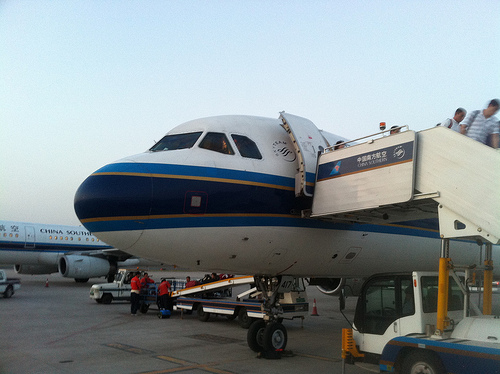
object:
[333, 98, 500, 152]
passenger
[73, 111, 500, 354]
plane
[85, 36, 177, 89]
sky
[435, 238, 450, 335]
pole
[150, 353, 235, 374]
line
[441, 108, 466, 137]
person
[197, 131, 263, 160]
window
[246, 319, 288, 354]
wheel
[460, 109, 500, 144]
shirt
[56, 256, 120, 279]
engine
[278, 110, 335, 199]
door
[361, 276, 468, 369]
truck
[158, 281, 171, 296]
shirt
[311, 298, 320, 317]
cone